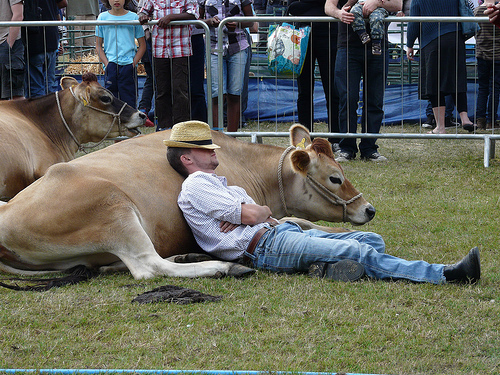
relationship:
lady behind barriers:
[407, 0, 479, 134] [2, 13, 484, 165]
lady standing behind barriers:
[407, 0, 479, 134] [2, 13, 493, 166]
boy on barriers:
[349, 0, 389, 54] [2, 13, 493, 166]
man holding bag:
[288, 0, 341, 147] [266, 20, 311, 79]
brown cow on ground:
[0, 71, 153, 203] [0, 122, 497, 374]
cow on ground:
[0, 123, 377, 290] [0, 122, 497, 374]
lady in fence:
[407, 0, 479, 134] [213, 13, 375, 123]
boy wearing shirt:
[84, 1, 159, 120] [89, 7, 154, 71]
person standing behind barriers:
[286, 1, 342, 156] [2, 13, 493, 166]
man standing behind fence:
[323, 0, 389, 164] [97, 9, 456, 191]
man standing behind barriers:
[323, 0, 389, 164] [2, 13, 493, 166]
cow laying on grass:
[0, 123, 377, 290] [0, 120, 497, 374]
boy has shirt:
[84, 1, 149, 122] [92, 8, 151, 64]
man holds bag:
[288, 0, 341, 147] [266, 20, 311, 79]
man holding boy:
[323, 0, 389, 164] [345, 0, 388, 56]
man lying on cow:
[165, 120, 488, 286] [0, 71, 381, 279]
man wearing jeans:
[165, 120, 483, 285] [292, 217, 437, 269]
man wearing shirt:
[165, 120, 483, 285] [178, 164, 282, 261]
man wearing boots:
[165, 120, 488, 286] [440, 247, 484, 291]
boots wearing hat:
[440, 247, 484, 291] [164, 110, 220, 150]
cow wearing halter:
[0, 123, 377, 290] [271, 140, 360, 225]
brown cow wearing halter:
[2, 71, 147, 205] [51, 87, 131, 152]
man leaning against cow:
[165, 120, 483, 285] [0, 123, 377, 290]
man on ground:
[165, 120, 483, 285] [0, 122, 497, 374]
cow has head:
[0, 123, 377, 290] [277, 121, 379, 228]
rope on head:
[267, 139, 294, 215] [277, 121, 379, 228]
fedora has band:
[162, 118, 224, 152] [176, 136, 216, 147]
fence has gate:
[209, 5, 494, 168] [212, 4, 498, 163]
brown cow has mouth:
[0, 71, 153, 203] [108, 104, 161, 146]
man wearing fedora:
[165, 120, 483, 285] [162, 118, 221, 150]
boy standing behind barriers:
[84, 1, 149, 122] [2, 13, 493, 166]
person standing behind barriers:
[137, 0, 200, 130] [2, 13, 493, 166]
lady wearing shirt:
[407, 0, 481, 136] [407, 0, 480, 42]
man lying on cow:
[165, 120, 488, 286] [0, 123, 377, 290]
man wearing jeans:
[165, 120, 483, 285] [245, 220, 449, 285]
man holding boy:
[323, 0, 399, 162] [349, 0, 389, 54]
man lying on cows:
[165, 120, 483, 285] [1, 40, 389, 294]